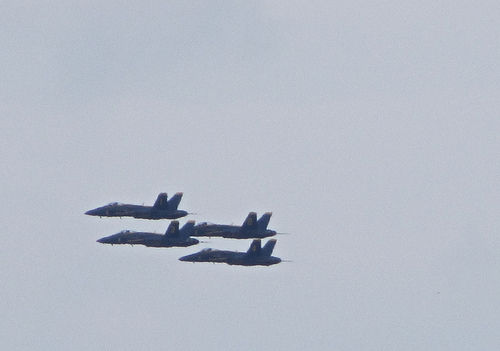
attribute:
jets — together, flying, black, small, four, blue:
[73, 183, 298, 282]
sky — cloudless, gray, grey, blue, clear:
[39, 74, 494, 329]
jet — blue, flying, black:
[86, 190, 183, 222]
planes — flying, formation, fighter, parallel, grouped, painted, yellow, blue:
[92, 190, 322, 277]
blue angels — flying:
[91, 191, 208, 251]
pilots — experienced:
[79, 194, 218, 235]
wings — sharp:
[132, 199, 190, 216]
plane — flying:
[63, 186, 205, 224]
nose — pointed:
[79, 203, 103, 219]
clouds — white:
[142, 42, 393, 139]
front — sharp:
[96, 229, 109, 249]